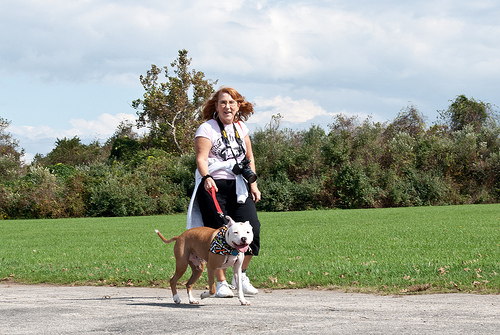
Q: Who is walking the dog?
A: The woman.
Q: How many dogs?
A: 1.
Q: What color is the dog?
A: Brown.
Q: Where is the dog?
A: The sidewalk.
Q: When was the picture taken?
A: Daytime.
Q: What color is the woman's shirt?
A: White.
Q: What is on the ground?
A: Concrete.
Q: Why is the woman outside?
A: Walking the dog.